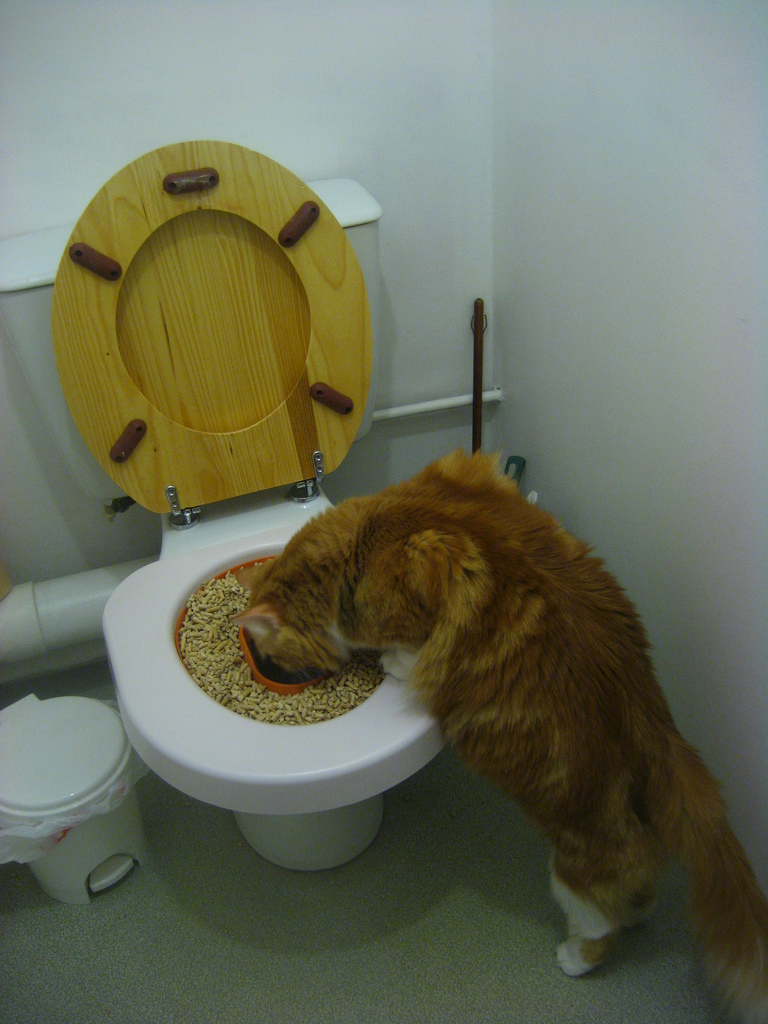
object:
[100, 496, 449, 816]
toilet bowl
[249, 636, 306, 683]
cat food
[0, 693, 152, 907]
trash can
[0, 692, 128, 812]
cover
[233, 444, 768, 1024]
cat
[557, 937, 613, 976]
foot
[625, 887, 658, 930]
foot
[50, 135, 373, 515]
toilet seat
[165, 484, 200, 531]
hinge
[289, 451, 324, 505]
hinge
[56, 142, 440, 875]
toilet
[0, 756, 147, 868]
trash bag